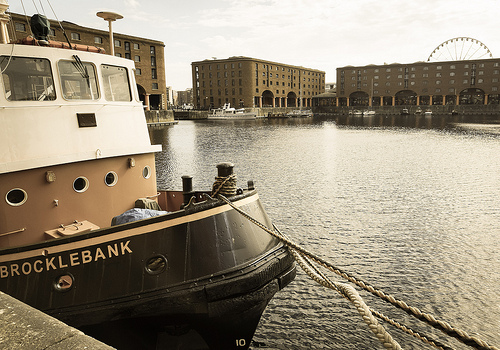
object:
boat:
[0, 14, 305, 350]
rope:
[205, 169, 500, 350]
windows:
[4, 54, 56, 101]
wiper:
[71, 49, 94, 87]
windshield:
[51, 62, 107, 102]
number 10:
[234, 336, 250, 349]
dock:
[0, 290, 126, 350]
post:
[213, 161, 238, 194]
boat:
[207, 102, 257, 119]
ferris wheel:
[427, 37, 495, 60]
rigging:
[21, 0, 126, 57]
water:
[156, 110, 499, 347]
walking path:
[251, 91, 298, 110]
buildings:
[191, 54, 325, 111]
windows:
[71, 180, 90, 192]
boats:
[284, 108, 314, 118]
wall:
[246, 98, 500, 117]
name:
[0, 242, 133, 281]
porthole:
[4, 186, 29, 207]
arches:
[392, 90, 416, 106]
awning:
[311, 92, 335, 98]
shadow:
[261, 106, 462, 127]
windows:
[373, 74, 379, 79]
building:
[334, 54, 499, 102]